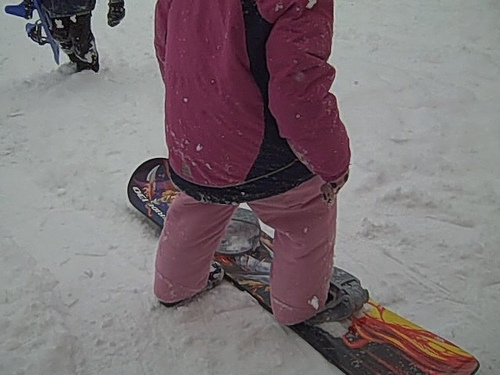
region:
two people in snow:
[4, 2, 496, 369]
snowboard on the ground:
[127, 154, 480, 374]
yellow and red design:
[369, 310, 469, 366]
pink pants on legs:
[154, 176, 339, 319]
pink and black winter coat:
[154, 2, 351, 202]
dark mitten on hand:
[104, 0, 125, 28]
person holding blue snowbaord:
[2, 1, 103, 73]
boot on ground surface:
[154, 260, 225, 309]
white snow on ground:
[2, 2, 497, 373]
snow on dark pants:
[53, 12, 100, 73]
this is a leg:
[154, 202, 223, 294]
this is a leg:
[280, 205, 331, 333]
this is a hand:
[291, 64, 346, 202]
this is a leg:
[106, 1, 127, 24]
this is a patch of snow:
[444, 154, 485, 204]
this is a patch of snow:
[83, 261, 107, 298]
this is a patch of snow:
[19, 145, 38, 344]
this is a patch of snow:
[37, 110, 105, 284]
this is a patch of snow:
[130, 328, 192, 355]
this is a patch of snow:
[370, 44, 404, 96]